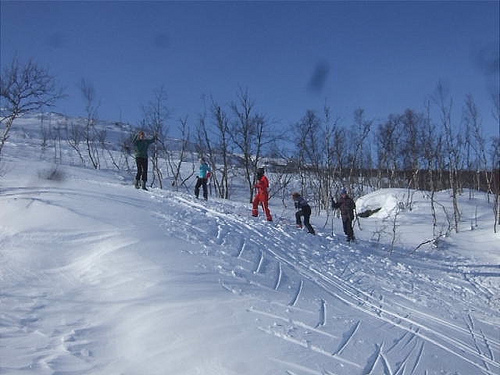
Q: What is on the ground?
A: Snow.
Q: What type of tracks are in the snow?
A: Ski.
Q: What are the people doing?
A: Skiing.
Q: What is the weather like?
A: Clear.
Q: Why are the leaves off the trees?
A: It is winter time.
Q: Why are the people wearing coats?
A: It is cold.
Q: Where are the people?
A: Standing on snowy hill.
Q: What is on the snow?
A: Track marks.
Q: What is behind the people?
A: Bare trees.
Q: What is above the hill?
A: Blue sky.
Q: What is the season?
A: Winter.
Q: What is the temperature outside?
A: Cold.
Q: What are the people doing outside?
A: Hiking up mountain.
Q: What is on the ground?
A: Snow.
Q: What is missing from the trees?
A: Leaves.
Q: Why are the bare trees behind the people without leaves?
A: Wintertime.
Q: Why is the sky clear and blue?
A: Very cold and it is winter.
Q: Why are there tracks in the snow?
A: Snow tractor.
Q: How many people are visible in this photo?
A: Five.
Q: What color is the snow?
A: White.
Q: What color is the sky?
A: Blue.